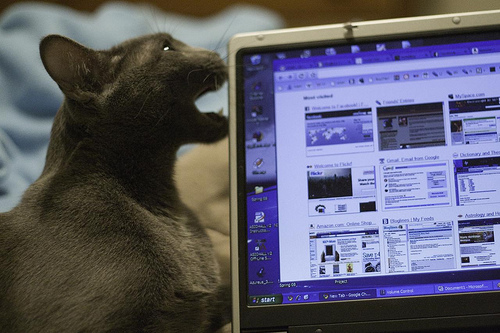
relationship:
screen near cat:
[253, 95, 476, 248] [32, 15, 255, 209]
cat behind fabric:
[32, 15, 255, 209] [111, 16, 137, 34]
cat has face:
[32, 15, 255, 209] [148, 47, 224, 115]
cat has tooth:
[32, 15, 255, 209] [203, 87, 231, 123]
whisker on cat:
[208, 32, 235, 33] [32, 15, 255, 209]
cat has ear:
[32, 15, 255, 209] [10, 28, 94, 109]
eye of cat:
[151, 37, 183, 61] [32, 15, 255, 209]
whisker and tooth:
[208, 32, 235, 33] [203, 87, 231, 123]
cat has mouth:
[32, 15, 255, 209] [189, 52, 241, 125]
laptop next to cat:
[240, 43, 486, 277] [32, 15, 255, 209]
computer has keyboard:
[240, 43, 486, 277] [409, 300, 478, 326]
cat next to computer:
[32, 15, 255, 209] [240, 43, 486, 277]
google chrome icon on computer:
[321, 281, 338, 300] [240, 43, 486, 277]